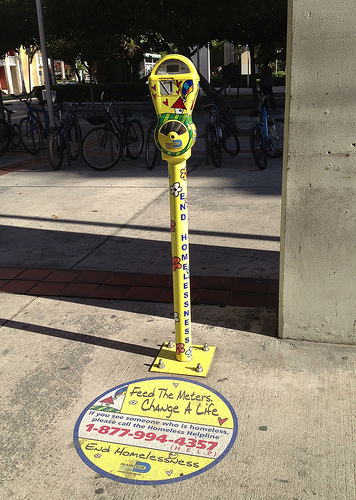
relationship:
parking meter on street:
[149, 50, 221, 377] [1, 293, 353, 498]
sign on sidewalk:
[74, 376, 237, 482] [0, 108, 353, 497]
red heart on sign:
[217, 415, 227, 425] [74, 376, 237, 482]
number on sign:
[81, 415, 221, 460] [69, 374, 249, 488]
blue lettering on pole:
[180, 192, 190, 344] [167, 162, 192, 361]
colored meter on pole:
[148, 53, 200, 162] [167, 162, 192, 361]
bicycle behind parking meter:
[16, 90, 56, 153] [136, 47, 225, 375]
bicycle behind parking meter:
[47, 99, 81, 166] [136, 47, 225, 375]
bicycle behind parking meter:
[85, 93, 142, 169] [136, 47, 225, 375]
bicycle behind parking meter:
[204, 92, 239, 165] [136, 47, 225, 375]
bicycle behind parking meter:
[250, 89, 278, 171] [136, 47, 225, 375]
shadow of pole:
[32, 191, 117, 291] [276, 2, 345, 342]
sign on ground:
[74, 376, 237, 482] [3, 85, 355, 496]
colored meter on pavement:
[148, 53, 200, 162] [2, 166, 345, 498]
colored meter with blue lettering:
[148, 53, 200, 162] [180, 187, 199, 365]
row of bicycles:
[1, 96, 278, 170] [200, 84, 281, 168]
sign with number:
[74, 376, 237, 482] [86, 424, 218, 451]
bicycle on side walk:
[250, 89, 278, 171] [1, 116, 354, 498]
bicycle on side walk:
[201, 92, 240, 168] [1, 116, 354, 498]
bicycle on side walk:
[81, 91, 144, 170] [1, 116, 354, 498]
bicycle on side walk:
[12, 90, 60, 155] [1, 116, 354, 498]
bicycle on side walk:
[47, 99, 81, 166] [1, 116, 354, 498]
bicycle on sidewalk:
[201, 92, 240, 168] [196, 161, 252, 196]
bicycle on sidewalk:
[81, 91, 144, 170] [56, 137, 249, 360]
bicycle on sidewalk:
[12, 90, 60, 155] [38, 102, 234, 324]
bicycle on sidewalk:
[12, 90, 60, 155] [0, 108, 353, 497]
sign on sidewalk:
[74, 376, 237, 482] [64, 325, 289, 498]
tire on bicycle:
[76, 130, 126, 166] [250, 89, 278, 171]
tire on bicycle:
[81, 127, 122, 171] [250, 89, 278, 171]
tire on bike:
[250, 126, 267, 170] [203, 78, 239, 172]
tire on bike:
[43, 120, 64, 171] [80, 86, 145, 180]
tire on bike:
[16, 113, 40, 156] [42, 93, 84, 179]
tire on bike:
[217, 115, 242, 157] [7, 82, 55, 159]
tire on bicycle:
[240, 89, 287, 171] [81, 91, 144, 170]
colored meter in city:
[148, 53, 200, 162] [1, 1, 354, 496]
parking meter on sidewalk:
[148, 53, 216, 378] [0, 108, 353, 497]